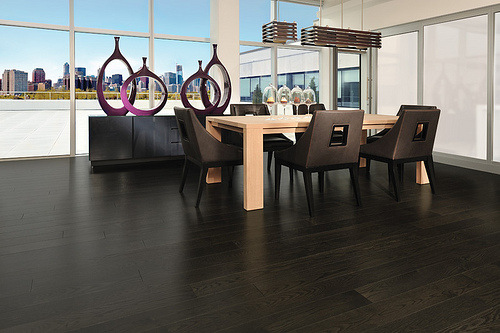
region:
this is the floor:
[79, 217, 186, 301]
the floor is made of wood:
[76, 231, 211, 291]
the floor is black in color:
[43, 207, 142, 299]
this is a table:
[220, 115, 266, 201]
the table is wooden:
[243, 131, 259, 211]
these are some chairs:
[149, 109, 447, 195]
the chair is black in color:
[313, 129, 325, 153]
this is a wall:
[409, 29, 490, 101]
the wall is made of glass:
[433, 33, 494, 95]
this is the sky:
[159, 7, 204, 38]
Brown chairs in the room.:
[175, 98, 437, 193]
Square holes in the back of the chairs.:
[326, 122, 439, 149]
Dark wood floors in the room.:
[1, 136, 499, 328]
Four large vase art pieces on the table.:
[93, 31, 233, 112]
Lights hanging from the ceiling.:
[259, 18, 391, 55]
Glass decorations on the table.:
[259, 76, 330, 117]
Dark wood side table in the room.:
[86, 110, 235, 169]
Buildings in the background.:
[3, 43, 213, 100]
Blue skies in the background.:
[3, 2, 330, 107]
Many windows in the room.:
[0, 0, 374, 110]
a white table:
[204, 102, 435, 210]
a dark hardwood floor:
[2, 148, 494, 327]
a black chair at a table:
[277, 110, 374, 212]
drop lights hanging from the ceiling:
[262, 17, 382, 52]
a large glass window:
[2, 3, 359, 109]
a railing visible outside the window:
[0, 85, 205, 100]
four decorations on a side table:
[90, 31, 240, 112]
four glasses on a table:
[255, 80, 312, 115]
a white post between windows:
[210, 0, 240, 145]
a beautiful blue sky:
[0, 2, 324, 84]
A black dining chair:
[282, 98, 380, 220]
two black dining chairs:
[290, 105, 447, 196]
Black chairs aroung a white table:
[202, 99, 418, 209]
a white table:
[211, 96, 278, 207]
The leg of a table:
[231, 123, 274, 225]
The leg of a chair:
[177, 166, 217, 208]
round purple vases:
[85, 26, 235, 112]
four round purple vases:
[89, 28, 240, 128]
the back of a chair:
[302, 113, 372, 183]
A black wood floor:
[155, 244, 381, 314]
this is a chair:
[307, 106, 371, 208]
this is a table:
[238, 107, 288, 140]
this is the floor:
[178, 225, 350, 306]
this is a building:
[3, 67, 21, 92]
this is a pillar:
[211, 15, 241, 35]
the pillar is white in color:
[220, 15, 232, 46]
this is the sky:
[18, 5, 57, 20]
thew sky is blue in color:
[87, 5, 127, 25]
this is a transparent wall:
[19, 30, 60, 148]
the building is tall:
[7, 69, 27, 104]